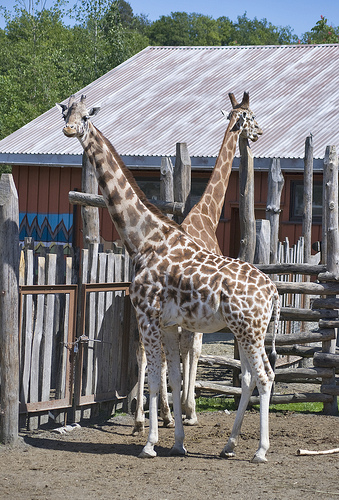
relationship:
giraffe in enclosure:
[44, 87, 282, 465] [9, 236, 338, 490]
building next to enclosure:
[3, 34, 332, 288] [9, 236, 338, 490]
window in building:
[289, 177, 329, 225] [3, 34, 332, 288]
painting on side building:
[23, 207, 77, 239] [3, 34, 332, 288]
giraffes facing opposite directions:
[44, 87, 282, 465] [48, 83, 272, 176]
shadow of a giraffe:
[23, 424, 204, 463] [44, 87, 282, 465]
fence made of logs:
[6, 246, 325, 421] [1, 148, 328, 395]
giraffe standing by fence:
[44, 87, 282, 465] [6, 246, 325, 421]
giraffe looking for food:
[44, 87, 282, 465] [273, 399, 325, 409]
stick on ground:
[296, 443, 337, 460] [2, 404, 335, 494]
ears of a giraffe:
[52, 99, 106, 118] [44, 87, 282, 465]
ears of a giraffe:
[218, 105, 255, 122] [179, 83, 276, 228]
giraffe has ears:
[44, 87, 282, 465] [52, 99, 106, 118]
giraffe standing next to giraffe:
[159, 85, 269, 252] [44, 87, 282, 465]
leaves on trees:
[16, 48, 49, 89] [3, 5, 115, 81]